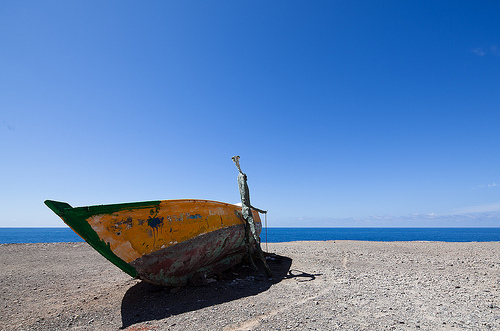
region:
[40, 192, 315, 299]
small boat sitting on the sand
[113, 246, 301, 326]
shadow from the boat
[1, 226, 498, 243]
bright blue body of water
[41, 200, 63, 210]
edge of the boat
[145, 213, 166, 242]
rust on the boat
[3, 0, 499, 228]
bright blue sky with very few clouds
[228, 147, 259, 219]
something sticking up off the boat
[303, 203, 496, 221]
small, thin cloud formation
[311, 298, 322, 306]
tiny rock on the ground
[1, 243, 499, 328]
rocky shore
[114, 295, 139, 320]
the shadow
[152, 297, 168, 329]
the shadow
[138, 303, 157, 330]
the shadow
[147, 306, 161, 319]
the shadow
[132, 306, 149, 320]
the shadow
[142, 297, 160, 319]
the shadow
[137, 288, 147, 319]
the shadow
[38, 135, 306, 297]
boat that has been washed ashore and left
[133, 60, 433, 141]
blue sky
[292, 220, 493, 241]
clear water in the distance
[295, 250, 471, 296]
sandy beach with rocks and sand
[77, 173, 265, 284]
yellow boat that is rusty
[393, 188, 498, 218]
clear cloudy sky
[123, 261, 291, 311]
shadow from boat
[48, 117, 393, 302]
boat washed ashore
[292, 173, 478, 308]
ocean and beach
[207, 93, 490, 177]
clear ocean sky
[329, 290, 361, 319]
THE PEBBLES ARE TINY WHITE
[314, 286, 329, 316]
THE PEBBLES ARE TINY WHITE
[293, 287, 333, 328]
THE PEBBLES ARE TINY WHITE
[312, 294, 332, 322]
THE PEBBLES ARE TINY WHITE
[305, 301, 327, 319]
THE PEBBLES ARE TINY WHITE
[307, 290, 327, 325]
THE PEBBLES ARE TINY WHITE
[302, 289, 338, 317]
THE PEBBLES ARE TINY WHITE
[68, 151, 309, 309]
boat on a beach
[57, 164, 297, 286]
boat painted green, yellow, red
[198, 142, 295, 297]
stick standing up against a boat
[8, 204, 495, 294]
water in background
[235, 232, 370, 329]
tracks in sand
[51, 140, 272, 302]
dirty boat on a beach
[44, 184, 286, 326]
boat casting shadow on sand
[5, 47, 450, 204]
blue skies in photograph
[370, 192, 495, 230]
some clouds on the horizon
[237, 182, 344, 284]
rope on tree branch